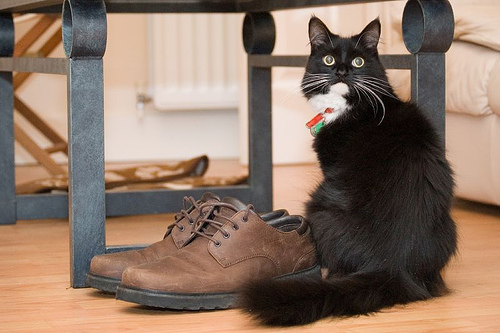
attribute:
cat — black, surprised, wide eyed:
[239, 16, 459, 327]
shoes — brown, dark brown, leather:
[84, 189, 319, 309]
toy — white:
[304, 83, 351, 134]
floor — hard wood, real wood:
[1, 166, 498, 331]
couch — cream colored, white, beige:
[382, 3, 499, 200]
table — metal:
[1, 0, 454, 288]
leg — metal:
[60, 1, 109, 285]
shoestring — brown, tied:
[192, 199, 236, 242]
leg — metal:
[243, 11, 275, 209]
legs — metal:
[1, 3, 454, 291]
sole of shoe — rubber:
[116, 285, 284, 313]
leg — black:
[402, 0, 453, 166]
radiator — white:
[147, 15, 268, 108]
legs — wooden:
[14, 18, 66, 179]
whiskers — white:
[353, 78, 396, 122]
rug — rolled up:
[18, 153, 247, 195]